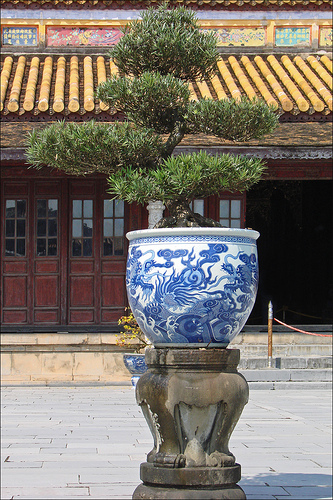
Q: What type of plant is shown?
A: Bonsai.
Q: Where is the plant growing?
A: A pot.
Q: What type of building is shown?
A: Oriental.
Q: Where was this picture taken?
A: A museum.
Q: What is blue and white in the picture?
A: The pot.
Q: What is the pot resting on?
A: A pedestal.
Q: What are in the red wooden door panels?
A: Glass.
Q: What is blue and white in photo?
A: Tree pot.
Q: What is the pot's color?
A: Blue and white.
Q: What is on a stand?
A: Pot.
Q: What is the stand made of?
A: Stone.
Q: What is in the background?
A: A building.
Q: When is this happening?
A: During the day time.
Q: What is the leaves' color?
A: Green.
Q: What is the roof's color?
A: Tan.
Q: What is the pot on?
A: Pedestal.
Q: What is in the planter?
A: A bonsai tree.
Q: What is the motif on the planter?
A: Asian.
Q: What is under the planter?
A: A stand.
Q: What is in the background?
A: A building.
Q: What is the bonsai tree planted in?
A: A blue and white planter.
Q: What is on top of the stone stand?
A: A planter.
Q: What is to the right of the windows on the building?
A: A doorway.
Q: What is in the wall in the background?
A: Windows.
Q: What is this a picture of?
A: A plant in a planter.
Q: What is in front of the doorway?
A: A satin rope.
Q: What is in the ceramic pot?
A: Tree.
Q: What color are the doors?
A: Red.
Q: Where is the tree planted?
A: Pot.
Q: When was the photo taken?
A: Daytime.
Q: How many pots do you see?
A: Two.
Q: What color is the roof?
A: Yellow.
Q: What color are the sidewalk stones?
A: Grey.